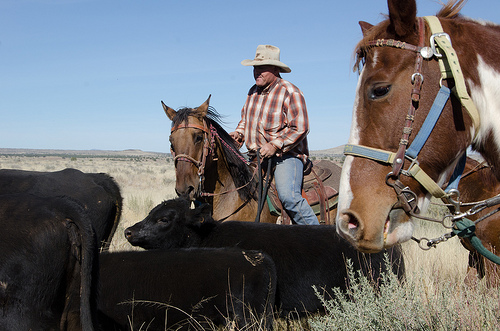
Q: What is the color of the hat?
A: Cream.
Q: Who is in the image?
A: Men and horses.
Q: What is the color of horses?
A: Brown.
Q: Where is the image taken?
A: In desert.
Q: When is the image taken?
A: Travelling.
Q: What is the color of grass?
A: Green.